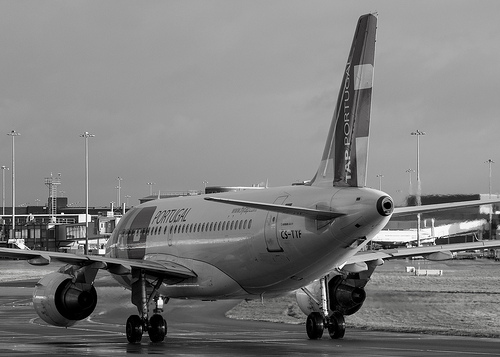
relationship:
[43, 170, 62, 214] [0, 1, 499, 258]
tower in background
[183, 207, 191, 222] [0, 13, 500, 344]
letter on airplane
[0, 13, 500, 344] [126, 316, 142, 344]
airplane has wheel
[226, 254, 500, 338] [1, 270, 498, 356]
grass next to tarmac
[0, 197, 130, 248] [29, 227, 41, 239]
building has window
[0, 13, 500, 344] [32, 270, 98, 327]
airplane has engine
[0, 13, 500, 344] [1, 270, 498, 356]
airplane on tarmac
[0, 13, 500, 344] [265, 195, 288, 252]
airplane has door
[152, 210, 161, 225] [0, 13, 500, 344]
letter on airplane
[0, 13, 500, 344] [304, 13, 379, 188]
airplane has tail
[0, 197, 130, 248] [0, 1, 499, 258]
building in background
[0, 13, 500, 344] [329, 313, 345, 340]
airplane has wheel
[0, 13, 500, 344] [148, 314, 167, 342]
airplane has wheel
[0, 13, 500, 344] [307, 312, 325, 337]
airplane has wheel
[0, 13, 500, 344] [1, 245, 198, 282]
airplane has wing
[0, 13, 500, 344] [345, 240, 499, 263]
airplane has wing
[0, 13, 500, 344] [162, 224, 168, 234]
airplane has window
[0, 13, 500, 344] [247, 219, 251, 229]
airplane has window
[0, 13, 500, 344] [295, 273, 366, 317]
airplane has engine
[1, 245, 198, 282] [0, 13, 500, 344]
wing on side of airplane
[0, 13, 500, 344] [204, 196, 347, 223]
airplane has wing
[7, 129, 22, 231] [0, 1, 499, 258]
lightpole in background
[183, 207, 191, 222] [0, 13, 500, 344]
letter on side of airplane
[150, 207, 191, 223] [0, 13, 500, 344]
word on side of airplane